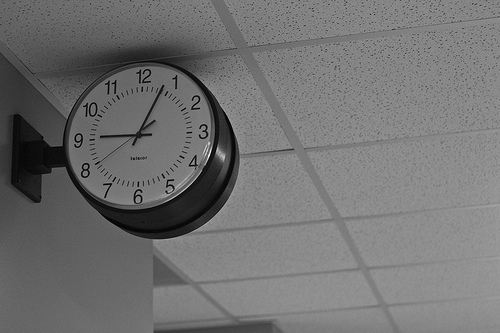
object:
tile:
[0, 1, 243, 77]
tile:
[242, 13, 500, 151]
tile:
[35, 47, 303, 161]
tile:
[298, 125, 498, 221]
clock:
[52, 54, 247, 246]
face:
[67, 63, 213, 207]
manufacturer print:
[124, 148, 149, 164]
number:
[122, 177, 157, 214]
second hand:
[96, 137, 153, 166]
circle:
[74, 78, 196, 183]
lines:
[109, 90, 119, 101]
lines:
[122, 86, 136, 103]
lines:
[129, 82, 146, 94]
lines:
[174, 95, 191, 122]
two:
[183, 89, 205, 115]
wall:
[0, 57, 155, 329]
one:
[169, 70, 183, 92]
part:
[93, 159, 106, 165]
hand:
[93, 118, 157, 170]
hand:
[133, 83, 162, 149]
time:
[51, 47, 212, 229]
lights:
[150, 251, 184, 286]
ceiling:
[1, 2, 496, 327]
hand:
[130, 82, 172, 150]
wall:
[10, 225, 115, 331]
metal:
[7, 113, 49, 204]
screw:
[13, 178, 21, 185]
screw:
[33, 188, 43, 202]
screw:
[38, 131, 47, 143]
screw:
[13, 110, 23, 125]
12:
[131, 62, 158, 84]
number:
[197, 122, 208, 139]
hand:
[78, 141, 128, 166]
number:
[97, 176, 121, 207]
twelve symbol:
[130, 62, 157, 91]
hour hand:
[97, 130, 154, 143]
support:
[20, 132, 93, 203]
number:
[69, 71, 220, 241]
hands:
[88, 79, 178, 156]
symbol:
[158, 175, 179, 197]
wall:
[6, 88, 57, 324]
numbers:
[82, 178, 190, 208]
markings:
[89, 143, 97, 146]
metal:
[109, 206, 195, 235]